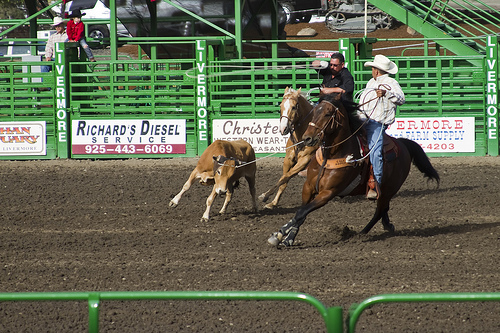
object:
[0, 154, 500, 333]
dirt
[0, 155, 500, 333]
ground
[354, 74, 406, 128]
shirt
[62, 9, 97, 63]
boy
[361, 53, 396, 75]
hat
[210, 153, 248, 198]
head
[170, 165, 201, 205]
cows leg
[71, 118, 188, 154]
sign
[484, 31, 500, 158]
pole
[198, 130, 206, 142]
letters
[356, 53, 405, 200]
cowboy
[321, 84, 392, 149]
reigns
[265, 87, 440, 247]
horse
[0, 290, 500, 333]
metal fence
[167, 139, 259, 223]
bull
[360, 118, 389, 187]
jeans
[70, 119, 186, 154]
ad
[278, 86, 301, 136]
horse's head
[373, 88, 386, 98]
hand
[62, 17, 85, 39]
shirt